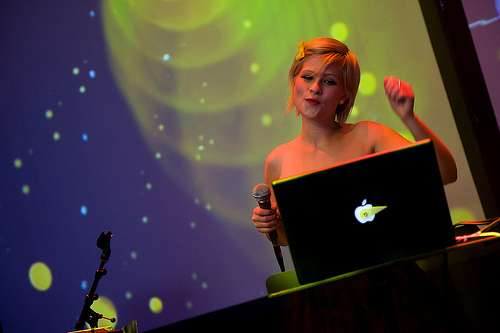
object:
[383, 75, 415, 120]
hand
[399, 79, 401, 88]
ring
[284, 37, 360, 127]
hair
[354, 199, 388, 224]
logo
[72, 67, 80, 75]
bubble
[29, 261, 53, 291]
bubble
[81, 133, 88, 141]
bubble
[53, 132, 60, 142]
bubble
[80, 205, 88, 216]
bubble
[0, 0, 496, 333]
screen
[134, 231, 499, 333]
table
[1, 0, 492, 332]
lights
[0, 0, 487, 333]
background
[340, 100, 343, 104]
earring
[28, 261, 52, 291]
spots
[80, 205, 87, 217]
spots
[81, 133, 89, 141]
spots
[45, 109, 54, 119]
spots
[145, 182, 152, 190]
spots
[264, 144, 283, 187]
bare shoulder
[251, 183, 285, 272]
microphone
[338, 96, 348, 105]
woman's ear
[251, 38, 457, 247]
woman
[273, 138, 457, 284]
computer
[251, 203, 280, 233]
hand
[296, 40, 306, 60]
bow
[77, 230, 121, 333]
microphone stand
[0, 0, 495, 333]
wall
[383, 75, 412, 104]
finger